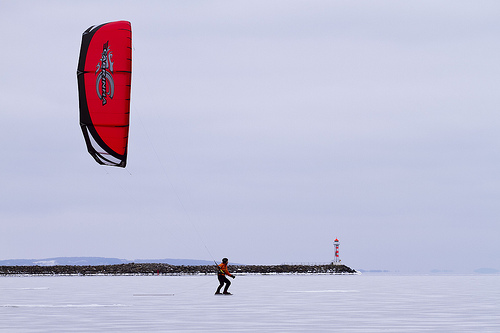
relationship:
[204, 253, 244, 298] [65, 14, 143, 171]
man attached parachute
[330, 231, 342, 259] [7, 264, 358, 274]
light house by rocks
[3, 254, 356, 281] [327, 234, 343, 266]
strip leading to lighthouse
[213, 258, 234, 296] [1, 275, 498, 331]
man parasailing into water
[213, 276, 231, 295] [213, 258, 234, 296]
legs are man